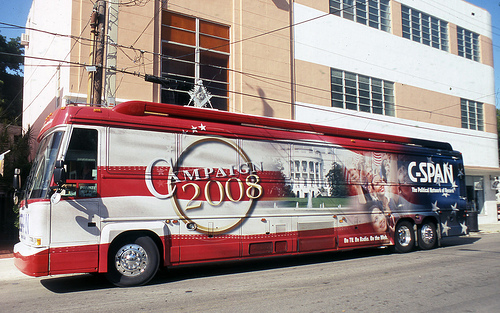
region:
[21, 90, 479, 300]
bus parked on the road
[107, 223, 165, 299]
wheels on the bus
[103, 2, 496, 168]
building next to the bus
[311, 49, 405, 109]
windows on the building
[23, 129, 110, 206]
window on the bus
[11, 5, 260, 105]
wires above the bus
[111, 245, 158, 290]
hubcap on the bus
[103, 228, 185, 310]
the tire is black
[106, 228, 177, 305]
the hubcap is silver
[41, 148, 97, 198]
mirror on a bus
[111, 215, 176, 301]
tire on a bus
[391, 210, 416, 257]
tire on a bus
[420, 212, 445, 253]
tire on a bus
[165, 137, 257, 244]
sign on a bus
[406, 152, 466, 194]
sign on a bus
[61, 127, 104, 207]
window on a bus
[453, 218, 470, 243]
star on a bus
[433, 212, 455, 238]
star on a bus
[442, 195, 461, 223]
star on a bus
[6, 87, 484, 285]
Large bus in street.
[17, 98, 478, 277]
Red, white and blue bus parked in street..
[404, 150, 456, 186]
The word 'C-SPAN' in white.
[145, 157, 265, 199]
The word 'Campaign' in white.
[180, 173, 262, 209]
The number '2008' in gold.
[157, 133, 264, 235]
Gold circle on side of bus.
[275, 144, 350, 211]
Image of White House and lawn on bus.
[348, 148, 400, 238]
Picture of people on side of bus.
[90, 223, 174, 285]
Front wheel of bus.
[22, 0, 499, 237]
White and beige building.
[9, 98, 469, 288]
A red white and blue bus.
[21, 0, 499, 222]
A tan and white building.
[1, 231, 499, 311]
A gray paved street.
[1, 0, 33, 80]
An area of blue sky.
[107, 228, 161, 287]
A front bus tire.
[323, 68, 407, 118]
A large multipaned window.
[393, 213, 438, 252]
Two rear bus tires.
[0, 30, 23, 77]
Part of a tree.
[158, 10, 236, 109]
A large building window.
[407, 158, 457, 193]
A white television logo.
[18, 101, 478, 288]
A red bus with white and blue markings.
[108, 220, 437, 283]
Three tires are on the ground.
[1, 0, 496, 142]
Wires are on the pole and overhead.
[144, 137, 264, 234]
A red and white campaign 2008 image.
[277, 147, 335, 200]
A sign with the image of the White House.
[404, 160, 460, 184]
C-SPAN in white letters on a blue background.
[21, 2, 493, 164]
A white building has pink stripes.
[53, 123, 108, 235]
Mirrors are making a shadow.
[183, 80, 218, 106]
A white symbol with inverted v's.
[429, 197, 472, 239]
Four white stars are on a blue surface.